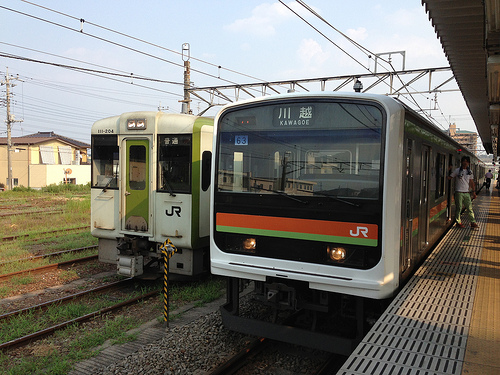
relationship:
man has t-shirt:
[447, 155, 477, 227] [451, 165, 476, 188]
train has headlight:
[208, 92, 498, 357] [324, 245, 348, 265]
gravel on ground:
[166, 329, 216, 369] [1, 196, 328, 373]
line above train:
[0, 0, 266, 130] [208, 92, 498, 357]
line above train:
[280, 1, 372, 72] [88, 112, 219, 277]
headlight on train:
[329, 243, 346, 265] [208, 92, 498, 357]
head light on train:
[244, 238, 256, 251] [208, 92, 498, 357]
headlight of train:
[330, 248, 347, 262] [213, 86, 477, 316]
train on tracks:
[208, 92, 485, 357] [0, 208, 160, 354]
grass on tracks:
[1, 181, 224, 370] [0, 185, 217, 364]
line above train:
[1, 8, 231, 85] [88, 112, 219, 277]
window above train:
[214, 96, 386, 270] [213, 86, 477, 316]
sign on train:
[272, 102, 317, 128] [208, 92, 498, 357]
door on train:
[124, 137, 152, 237] [88, 112, 219, 277]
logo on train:
[345, 222, 372, 242] [213, 86, 477, 316]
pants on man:
[451, 187, 478, 225] [448, 154, 480, 231]